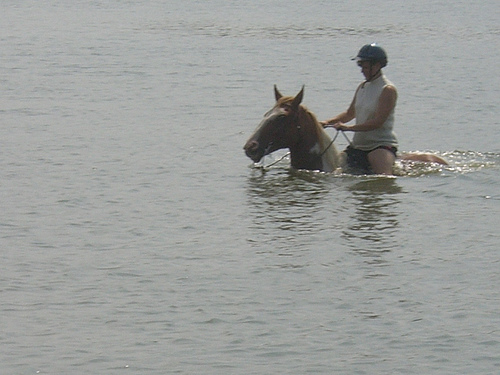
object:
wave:
[316, 298, 425, 357]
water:
[259, 199, 385, 269]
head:
[351, 44, 391, 79]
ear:
[273, 85, 283, 101]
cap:
[348, 43, 396, 64]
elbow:
[351, 84, 394, 146]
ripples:
[254, 149, 498, 180]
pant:
[346, 144, 398, 169]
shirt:
[350, 77, 403, 149]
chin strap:
[358, 70, 382, 80]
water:
[113, 31, 325, 82]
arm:
[353, 87, 399, 132]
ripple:
[196, 188, 338, 268]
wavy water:
[417, 220, 471, 257]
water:
[231, 187, 393, 247]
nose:
[243, 140, 257, 150]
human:
[316, 41, 399, 178]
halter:
[319, 121, 354, 156]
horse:
[241, 83, 449, 175]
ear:
[294, 85, 305, 107]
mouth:
[246, 142, 265, 162]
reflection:
[242, 165, 423, 262]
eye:
[276, 113, 288, 123]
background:
[14, 13, 484, 86]